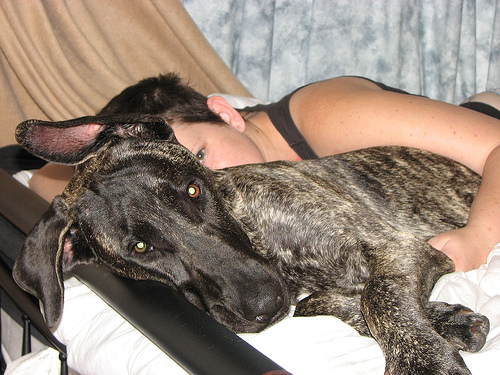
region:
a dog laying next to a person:
[13, 71, 493, 366]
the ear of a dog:
[10, 211, 81, 334]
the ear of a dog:
[10, 115, 172, 170]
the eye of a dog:
[180, 174, 206, 204]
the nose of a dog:
[246, 282, 286, 332]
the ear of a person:
[203, 88, 250, 136]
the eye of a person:
[187, 134, 213, 168]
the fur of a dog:
[281, 178, 367, 239]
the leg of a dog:
[352, 241, 465, 373]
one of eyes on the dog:
[183, 181, 195, 197]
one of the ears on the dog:
[18, 118, 98, 158]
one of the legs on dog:
[368, 251, 448, 373]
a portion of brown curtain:
[20, 17, 101, 86]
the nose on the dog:
[247, 287, 288, 325]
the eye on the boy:
[193, 144, 207, 161]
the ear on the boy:
[210, 101, 242, 127]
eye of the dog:
[153, 164, 215, 217]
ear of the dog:
[6, 201, 82, 305]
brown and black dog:
[236, 147, 403, 265]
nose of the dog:
[225, 259, 302, 336]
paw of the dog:
[345, 262, 447, 358]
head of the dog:
[36, 137, 299, 360]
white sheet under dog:
[266, 305, 353, 364]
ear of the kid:
[192, 72, 269, 142]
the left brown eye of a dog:
[184, 182, 200, 197]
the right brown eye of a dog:
[132, 241, 147, 255]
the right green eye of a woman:
[196, 148, 206, 163]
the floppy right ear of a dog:
[12, 214, 81, 328]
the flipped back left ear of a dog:
[12, 117, 182, 163]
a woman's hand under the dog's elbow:
[418, 227, 485, 277]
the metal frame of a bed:
[0, 170, 305, 372]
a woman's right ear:
[207, 91, 247, 133]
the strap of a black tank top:
[265, 100, 318, 162]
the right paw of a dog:
[432, 301, 489, 355]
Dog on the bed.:
[0, 110, 492, 373]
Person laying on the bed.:
[87, 70, 498, 187]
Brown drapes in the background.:
[2, 0, 262, 150]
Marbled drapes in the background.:
[177, 1, 498, 115]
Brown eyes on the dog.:
[121, 171, 215, 271]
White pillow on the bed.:
[63, 265, 386, 372]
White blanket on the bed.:
[430, 238, 499, 340]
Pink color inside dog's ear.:
[13, 110, 113, 167]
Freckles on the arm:
[367, 82, 489, 164]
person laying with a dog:
[3, 56, 499, 368]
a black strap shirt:
[242, 82, 319, 163]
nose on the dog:
[223, 263, 296, 324]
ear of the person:
[200, 86, 252, 133]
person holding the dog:
[72, 48, 499, 271]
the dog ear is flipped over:
[0, 100, 177, 175]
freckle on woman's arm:
[472, 131, 479, 138]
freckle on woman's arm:
[449, 130, 456, 138]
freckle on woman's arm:
[428, 110, 441, 124]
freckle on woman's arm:
[391, 102, 401, 114]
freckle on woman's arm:
[406, 96, 414, 103]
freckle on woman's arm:
[482, 226, 493, 238]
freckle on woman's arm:
[478, 204, 484, 212]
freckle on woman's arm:
[491, 197, 497, 205]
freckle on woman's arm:
[471, 130, 478, 140]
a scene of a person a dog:
[36, 39, 459, 346]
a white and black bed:
[3, 121, 447, 372]